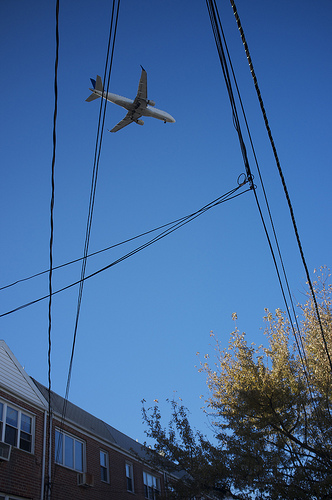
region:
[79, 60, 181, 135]
An airplane flying in the sky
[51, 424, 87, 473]
Triple-paned window reflects the blue sky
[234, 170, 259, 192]
Wiring loops around more wires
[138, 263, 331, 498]
Large tree partially in the sun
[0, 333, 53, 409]
White siding on the pitched roof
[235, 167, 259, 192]
Horizontal wires attached to vertical wires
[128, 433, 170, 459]
3 white chimneys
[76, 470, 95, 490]
Very rusty air conditioning unit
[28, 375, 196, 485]
Black roof tiles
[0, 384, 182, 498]
Red bricks on side of building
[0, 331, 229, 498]
the building is brick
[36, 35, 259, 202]
an airplane in the sky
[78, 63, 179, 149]
the airplane is gray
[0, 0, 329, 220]
the sky is clear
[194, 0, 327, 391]
the power lines are black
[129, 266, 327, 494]
the tree is green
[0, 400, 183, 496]
the building has windows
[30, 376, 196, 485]
the roof is shingled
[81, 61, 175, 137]
the airplane has wings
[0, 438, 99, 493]
the building has air conditioning units on it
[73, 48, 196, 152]
a commercial plane in flight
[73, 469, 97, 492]
a rusty metal box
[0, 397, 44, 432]
a few half closed blinds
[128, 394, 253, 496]
tree branch covered in leaves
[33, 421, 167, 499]
a row of windows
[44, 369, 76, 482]
a few electrical wires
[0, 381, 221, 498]
brick building with a black roof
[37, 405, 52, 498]
a white drainage pipe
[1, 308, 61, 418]
some white house siding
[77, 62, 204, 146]
a blue and white plane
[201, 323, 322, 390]
Sun shining on tree leaves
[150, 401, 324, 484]
Leaves and branches on a tree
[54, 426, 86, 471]
Window on a brick building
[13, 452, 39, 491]
Bricks on the wall of a building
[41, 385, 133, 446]
Roof of a building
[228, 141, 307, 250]
Utility wires in the sky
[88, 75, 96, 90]
Blue tail fin of an airplane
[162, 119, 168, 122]
Front wheel of a plane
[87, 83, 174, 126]
Underside of a plane in the sky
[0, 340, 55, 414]
White siding on a brick building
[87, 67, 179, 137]
a plane flying by in the sky above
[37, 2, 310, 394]
many power lines in the sky above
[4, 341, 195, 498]
the house off to the side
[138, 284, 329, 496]
a leafy tree partially in shadow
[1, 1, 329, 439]
the blue sky above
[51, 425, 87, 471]
the window of the building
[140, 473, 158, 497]
another window of the building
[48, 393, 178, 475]
the roof to the building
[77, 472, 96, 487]
the air condiitong in the wall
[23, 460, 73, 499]
part of the wall